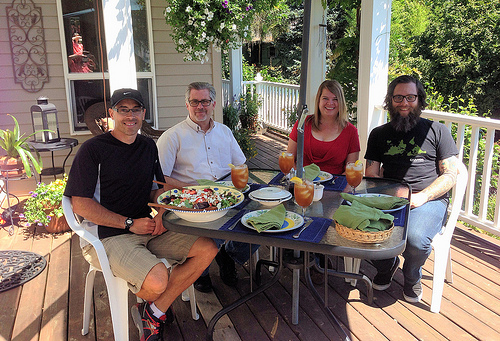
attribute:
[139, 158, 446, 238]
table — square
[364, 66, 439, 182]
man — bearded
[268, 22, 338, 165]
woman — sitting, smiling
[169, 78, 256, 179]
gentleman — sitting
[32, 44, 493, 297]
people — smiling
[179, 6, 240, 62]
plant — hanging, potted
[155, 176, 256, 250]
bowl — white, here, large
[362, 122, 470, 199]
shirt — black, green, red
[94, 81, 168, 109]
cap — worn, black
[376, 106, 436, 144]
beard — heavy, gray, grey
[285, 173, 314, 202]
glass — here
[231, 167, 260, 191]
drink — iced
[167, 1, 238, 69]
flowers — hanging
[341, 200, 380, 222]
napkin — green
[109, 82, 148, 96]
hat — black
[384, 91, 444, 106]
glasses — worn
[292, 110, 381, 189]
shirt — red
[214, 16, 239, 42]
flower — hanging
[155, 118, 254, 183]
shirt — white